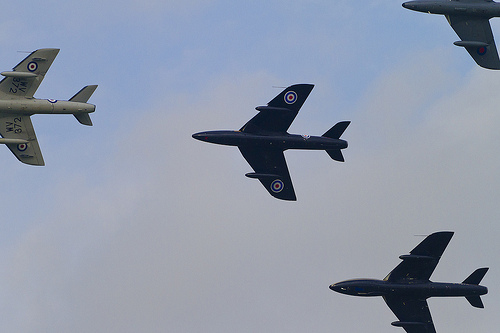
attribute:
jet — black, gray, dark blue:
[182, 77, 360, 207]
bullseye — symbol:
[280, 87, 302, 108]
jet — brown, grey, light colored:
[0, 44, 101, 174]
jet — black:
[321, 226, 496, 332]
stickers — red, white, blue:
[283, 90, 299, 104]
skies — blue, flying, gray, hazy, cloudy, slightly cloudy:
[1, 0, 498, 330]